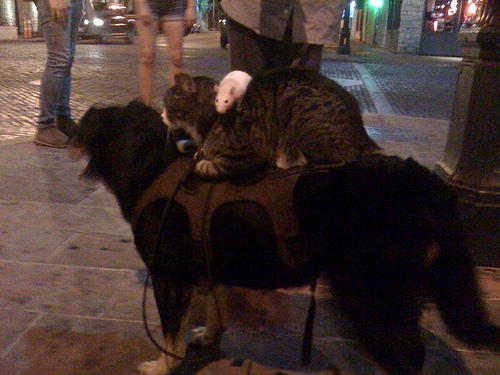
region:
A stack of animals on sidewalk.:
[64, 58, 494, 373]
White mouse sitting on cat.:
[208, 65, 262, 117]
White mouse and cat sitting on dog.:
[158, 63, 388, 183]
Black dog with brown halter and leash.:
[72, 96, 492, 367]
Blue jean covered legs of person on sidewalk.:
[32, 9, 84, 166]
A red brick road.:
[381, 64, 448, 116]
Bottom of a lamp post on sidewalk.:
[437, 17, 499, 213]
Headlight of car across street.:
[76, 3, 143, 49]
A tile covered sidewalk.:
[10, 177, 106, 365]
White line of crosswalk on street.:
[348, 53, 404, 127]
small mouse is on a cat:
[204, 64, 253, 119]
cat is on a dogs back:
[151, 67, 386, 184]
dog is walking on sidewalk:
[60, 90, 494, 374]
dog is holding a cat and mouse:
[63, 88, 498, 373]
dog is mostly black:
[69, 85, 496, 374]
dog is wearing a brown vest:
[66, 91, 499, 371]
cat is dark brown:
[158, 66, 392, 188]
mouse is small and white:
[207, 61, 254, 118]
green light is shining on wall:
[366, 1, 388, 21]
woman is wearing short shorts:
[136, 0, 188, 30]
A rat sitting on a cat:
[214, 70, 249, 112]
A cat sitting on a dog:
[163, 75, 374, 169]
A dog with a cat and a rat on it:
[74, 112, 496, 369]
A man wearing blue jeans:
[40, 6, 76, 143]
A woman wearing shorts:
[130, 5, 186, 101]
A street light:
[439, 4, 497, 261]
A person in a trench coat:
[218, 2, 338, 74]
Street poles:
[21, 15, 33, 40]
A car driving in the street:
[83, 10, 136, 42]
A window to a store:
[419, 2, 469, 29]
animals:
[59, 18, 497, 373]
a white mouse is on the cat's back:
[160, 63, 405, 180]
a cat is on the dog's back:
[71, 61, 483, 371]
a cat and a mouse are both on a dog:
[72, 65, 482, 373]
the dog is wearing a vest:
[58, 100, 480, 367]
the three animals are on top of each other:
[44, 61, 499, 373]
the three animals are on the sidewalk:
[59, 59, 486, 373]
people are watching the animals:
[31, 3, 353, 144]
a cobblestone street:
[16, 38, 469, 135]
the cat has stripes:
[162, 67, 385, 174]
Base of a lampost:
[431, 14, 498, 240]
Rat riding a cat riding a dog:
[69, 63, 490, 369]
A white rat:
[213, 65, 252, 115]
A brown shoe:
[32, 121, 74, 153]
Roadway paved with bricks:
[383, 65, 451, 115]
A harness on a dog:
[125, 153, 315, 294]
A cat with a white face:
[158, 69, 211, 156]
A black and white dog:
[64, 101, 496, 366]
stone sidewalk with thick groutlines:
[2, 196, 111, 365]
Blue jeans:
[35, 1, 80, 126]